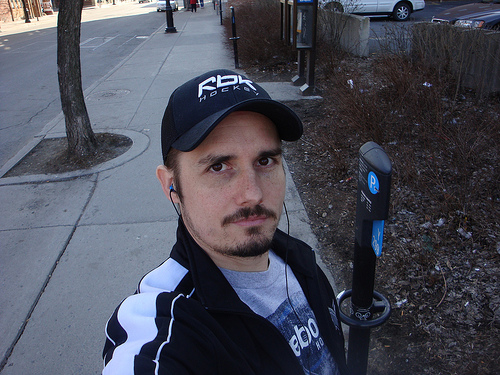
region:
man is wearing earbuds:
[163, 176, 240, 218]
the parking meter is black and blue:
[333, 130, 418, 328]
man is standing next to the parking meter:
[244, 151, 422, 357]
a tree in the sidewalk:
[41, 90, 182, 215]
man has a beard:
[175, 196, 343, 303]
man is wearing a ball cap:
[173, 38, 298, 119]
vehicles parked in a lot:
[434, 2, 499, 49]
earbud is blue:
[147, 175, 189, 204]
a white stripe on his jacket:
[122, 250, 199, 367]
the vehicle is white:
[320, 0, 438, 12]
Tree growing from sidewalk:
[52, 20, 124, 185]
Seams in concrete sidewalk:
[32, 188, 113, 260]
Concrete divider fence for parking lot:
[340, 8, 376, 64]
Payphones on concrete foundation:
[268, 0, 319, 101]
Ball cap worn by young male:
[152, 63, 307, 153]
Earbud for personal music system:
[164, 181, 185, 207]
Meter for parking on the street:
[345, 140, 397, 265]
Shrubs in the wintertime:
[377, 35, 454, 139]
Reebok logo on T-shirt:
[270, 303, 328, 360]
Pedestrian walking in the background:
[182, 0, 204, 15]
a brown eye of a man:
[204, 158, 227, 170]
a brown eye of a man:
[255, 155, 273, 164]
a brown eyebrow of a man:
[198, 151, 234, 161]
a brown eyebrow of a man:
[258, 148, 283, 158]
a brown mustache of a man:
[222, 198, 277, 223]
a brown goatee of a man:
[218, 230, 278, 249]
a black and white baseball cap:
[162, 73, 305, 153]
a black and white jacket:
[106, 217, 350, 367]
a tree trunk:
[52, 3, 96, 159]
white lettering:
[195, 66, 254, 104]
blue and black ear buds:
[151, 177, 193, 210]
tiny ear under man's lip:
[238, 219, 264, 239]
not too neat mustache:
[215, 194, 302, 225]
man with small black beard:
[201, 232, 288, 262]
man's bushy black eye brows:
[196, 151, 243, 162]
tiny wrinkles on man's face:
[212, 115, 278, 140]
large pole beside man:
[346, 131, 413, 260]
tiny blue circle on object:
[356, 169, 402, 198]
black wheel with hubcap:
[376, 1, 434, 29]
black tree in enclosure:
[15, 103, 150, 178]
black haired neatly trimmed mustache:
[213, 196, 283, 227]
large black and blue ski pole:
[314, 130, 408, 368]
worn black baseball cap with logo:
[148, 57, 307, 160]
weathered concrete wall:
[319, 12, 371, 62]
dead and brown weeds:
[340, 106, 462, 157]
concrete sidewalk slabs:
[9, 190, 103, 354]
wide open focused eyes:
[194, 152, 289, 182]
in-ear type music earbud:
[155, 170, 184, 204]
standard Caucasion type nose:
[231, 156, 264, 210]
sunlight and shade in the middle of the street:
[87, 4, 147, 31]